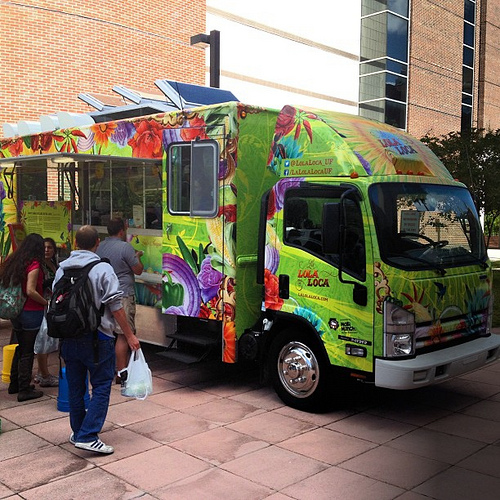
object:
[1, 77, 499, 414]
food truck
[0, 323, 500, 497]
road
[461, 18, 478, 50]
window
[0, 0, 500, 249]
building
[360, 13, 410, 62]
window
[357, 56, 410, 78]
window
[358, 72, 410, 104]
window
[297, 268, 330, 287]
lola loca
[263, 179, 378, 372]
door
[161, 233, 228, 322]
picture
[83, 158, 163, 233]
window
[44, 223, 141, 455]
man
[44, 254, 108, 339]
backpack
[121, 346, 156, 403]
bag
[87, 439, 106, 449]
stripes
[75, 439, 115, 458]
shoe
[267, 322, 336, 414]
wheel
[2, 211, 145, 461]
people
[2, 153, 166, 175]
awning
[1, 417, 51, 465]
square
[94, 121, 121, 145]
design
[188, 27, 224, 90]
light post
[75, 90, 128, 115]
vent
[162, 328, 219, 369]
steps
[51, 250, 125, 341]
hoody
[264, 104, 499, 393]
cab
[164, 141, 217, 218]
window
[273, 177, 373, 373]
passenger side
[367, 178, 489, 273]
windshield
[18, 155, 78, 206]
back window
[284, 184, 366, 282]
window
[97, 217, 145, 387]
man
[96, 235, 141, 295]
shirt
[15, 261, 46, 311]
shirt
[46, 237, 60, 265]
hair